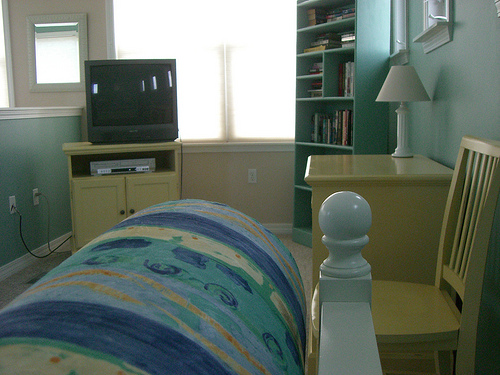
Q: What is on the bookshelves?
A: Books.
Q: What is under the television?
A: VCR.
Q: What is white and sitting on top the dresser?
A: Lamp.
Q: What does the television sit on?
A: Stand.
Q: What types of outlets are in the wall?
A: Electrical.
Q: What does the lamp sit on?
A: Dresser.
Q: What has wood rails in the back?
A: Chair.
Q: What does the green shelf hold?
A: Books.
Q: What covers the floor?
A: Carpet.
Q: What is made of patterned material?
A: Comforter.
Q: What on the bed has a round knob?
A: Post.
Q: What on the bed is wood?
A: Post.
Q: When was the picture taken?
A: During daylight hours.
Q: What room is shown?
A: A bedroom.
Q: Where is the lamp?
A: On the dresser.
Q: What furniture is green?
A: Bookshelf.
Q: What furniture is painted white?
A: Bed.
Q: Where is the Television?
A: On the wooden stand.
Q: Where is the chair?
A: Next to the dresser.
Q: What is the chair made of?
A: Wood.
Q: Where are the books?
A: On the bookshelf.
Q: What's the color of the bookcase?
A: Green.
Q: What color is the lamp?
A: White.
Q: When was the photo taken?
A: Daytime.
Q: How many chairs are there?
A: One.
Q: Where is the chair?
A: Near the table.